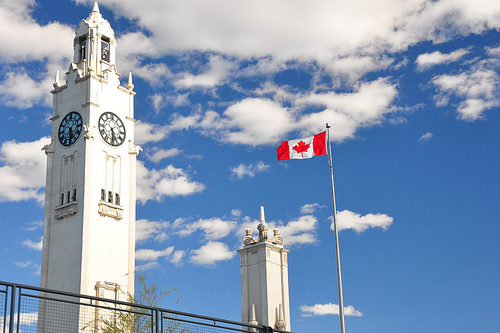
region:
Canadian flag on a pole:
[273, 137, 352, 163]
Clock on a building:
[97, 116, 131, 153]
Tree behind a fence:
[101, 273, 178, 330]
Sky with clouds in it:
[199, 54, 386, 158]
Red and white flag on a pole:
[266, 122, 341, 166]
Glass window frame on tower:
[91, 30, 113, 73]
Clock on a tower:
[44, 83, 135, 160]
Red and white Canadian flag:
[273, 121, 338, 167]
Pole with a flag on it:
[320, 134, 340, 274]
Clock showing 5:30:
[97, 106, 127, 151]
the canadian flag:
[278, 130, 327, 160]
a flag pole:
[320, 121, 352, 330]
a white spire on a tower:
[70, 0, 118, 68]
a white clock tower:
[38, 0, 140, 331]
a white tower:
[235, 200, 289, 331]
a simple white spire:
[255, 204, 270, 239]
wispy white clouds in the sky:
[0, 0, 498, 263]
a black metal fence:
[1, 278, 295, 332]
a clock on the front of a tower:
[97, 109, 126, 145]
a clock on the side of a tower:
[55, 112, 82, 147]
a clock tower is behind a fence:
[34, 0, 158, 332]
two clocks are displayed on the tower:
[56, 108, 126, 150]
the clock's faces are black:
[53, 108, 130, 147]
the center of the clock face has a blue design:
[101, 116, 121, 138]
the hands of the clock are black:
[105, 121, 120, 145]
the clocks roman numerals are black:
[54, 108, 126, 147]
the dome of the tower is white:
[73, 11, 115, 38]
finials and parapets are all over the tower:
[34, 15, 144, 222]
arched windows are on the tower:
[48, 185, 125, 210]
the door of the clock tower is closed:
[92, 276, 120, 331]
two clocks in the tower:
[50, 113, 135, 144]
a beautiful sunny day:
[156, 45, 490, 122]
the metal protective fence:
[0, 281, 269, 331]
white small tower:
[236, 210, 292, 325]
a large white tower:
[46, 39, 138, 324]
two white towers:
[47, 37, 289, 327]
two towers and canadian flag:
[46, 49, 347, 331]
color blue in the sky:
[407, 204, 497, 301]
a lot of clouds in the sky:
[143, 40, 383, 140]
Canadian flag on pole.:
[275, 131, 327, 166]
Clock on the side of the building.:
[97, 110, 126, 150]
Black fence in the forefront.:
[1, 274, 271, 331]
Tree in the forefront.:
[83, 274, 203, 331]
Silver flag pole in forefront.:
[322, 121, 349, 331]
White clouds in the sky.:
[0, 0, 494, 324]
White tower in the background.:
[36, 5, 142, 331]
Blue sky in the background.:
[2, 1, 497, 329]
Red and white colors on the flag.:
[274, 131, 327, 162]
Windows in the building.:
[97, 188, 122, 208]